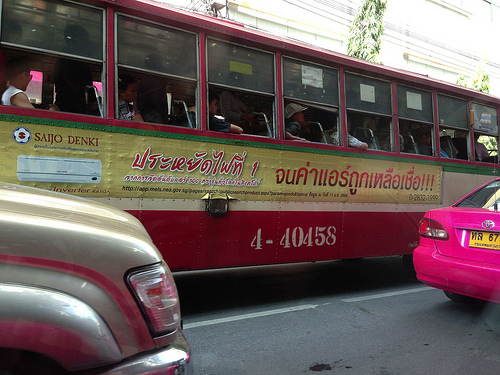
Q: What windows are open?
A: The bus windows.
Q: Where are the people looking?
A: Out the window.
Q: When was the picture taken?
A: In the day light.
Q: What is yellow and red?
A: The bus.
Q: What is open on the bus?
A: The windows.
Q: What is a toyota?
A: The pink car.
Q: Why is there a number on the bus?
A: Identification.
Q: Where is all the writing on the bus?
A: Down the side.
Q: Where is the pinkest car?
A: Beside a bus.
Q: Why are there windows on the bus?
A: To look through.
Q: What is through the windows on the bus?
A: People sitting.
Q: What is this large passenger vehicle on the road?
A: Bus.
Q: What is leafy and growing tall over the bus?
A: Trees.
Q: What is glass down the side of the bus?
A: Windows.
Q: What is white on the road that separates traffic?
A: Line.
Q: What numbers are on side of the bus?
A: 4-40458.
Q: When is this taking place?
A: Daytime.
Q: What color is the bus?
A: Red, gold and green.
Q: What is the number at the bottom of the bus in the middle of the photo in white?
A: 4-40458.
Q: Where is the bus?
A: Street.